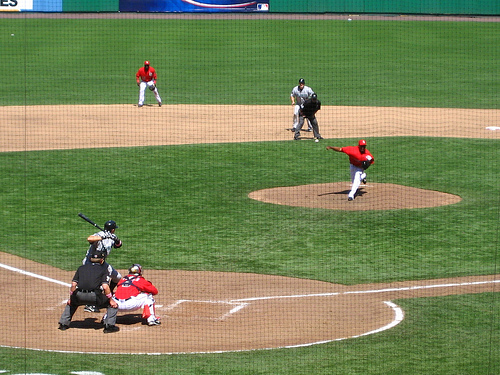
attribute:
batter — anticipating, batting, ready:
[76, 211, 124, 266]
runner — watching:
[289, 76, 322, 134]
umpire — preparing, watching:
[55, 249, 124, 335]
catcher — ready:
[104, 261, 160, 329]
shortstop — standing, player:
[292, 92, 328, 145]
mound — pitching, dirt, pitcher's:
[245, 171, 463, 215]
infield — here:
[4, 139, 497, 268]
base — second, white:
[483, 124, 499, 135]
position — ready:
[100, 266, 160, 326]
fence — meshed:
[6, 0, 499, 31]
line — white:
[230, 274, 500, 303]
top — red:
[346, 143, 379, 169]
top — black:
[71, 257, 118, 293]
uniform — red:
[337, 148, 375, 193]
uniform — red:
[114, 273, 164, 318]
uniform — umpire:
[61, 263, 117, 325]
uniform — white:
[292, 87, 316, 125]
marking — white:
[159, 292, 245, 325]